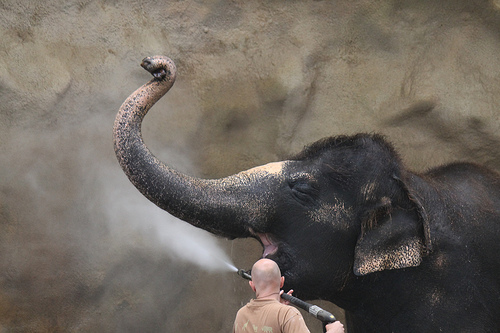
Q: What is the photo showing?
A: It is showing a zoo.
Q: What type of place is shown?
A: It is a zoo.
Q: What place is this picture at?
A: It is at the zoo.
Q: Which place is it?
A: It is a zoo.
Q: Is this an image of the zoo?
A: Yes, it is showing the zoo.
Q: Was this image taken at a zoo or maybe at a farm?
A: It was taken at a zoo.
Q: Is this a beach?
A: No, it is a zoo.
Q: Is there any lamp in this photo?
A: No, there are no lamps.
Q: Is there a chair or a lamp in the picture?
A: No, there are no lamps or chairs.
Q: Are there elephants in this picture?
A: Yes, there is an elephant.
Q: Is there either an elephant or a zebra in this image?
A: Yes, there is an elephant.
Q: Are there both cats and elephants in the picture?
A: No, there is an elephant but no cats.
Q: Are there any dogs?
A: No, there are no dogs.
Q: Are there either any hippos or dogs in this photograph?
A: No, there are no dogs or hippos.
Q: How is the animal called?
A: The animal is an elephant.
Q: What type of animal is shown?
A: The animal is an elephant.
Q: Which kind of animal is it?
A: The animal is an elephant.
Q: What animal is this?
A: That is an elephant.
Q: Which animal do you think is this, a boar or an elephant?
A: That is an elephant.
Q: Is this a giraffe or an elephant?
A: This is an elephant.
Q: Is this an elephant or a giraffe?
A: This is an elephant.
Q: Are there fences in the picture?
A: No, there are no fences.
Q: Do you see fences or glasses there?
A: No, there are no fences or glasses.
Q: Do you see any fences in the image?
A: No, there are no fences.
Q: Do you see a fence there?
A: No, there are no fences.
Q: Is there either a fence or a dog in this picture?
A: No, there are no fences or dogs.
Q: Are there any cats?
A: No, there are no cats.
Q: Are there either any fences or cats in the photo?
A: No, there are no cats or fences.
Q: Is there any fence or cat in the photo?
A: No, there are no cats or fences.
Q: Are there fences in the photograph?
A: No, there are no fences.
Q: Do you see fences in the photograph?
A: No, there are no fences.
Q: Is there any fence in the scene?
A: No, there are no fences.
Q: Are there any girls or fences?
A: No, there are no fences or girls.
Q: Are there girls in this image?
A: No, there are no girls.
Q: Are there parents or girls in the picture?
A: No, there are no girls or parents.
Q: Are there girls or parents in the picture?
A: No, there are no girls or parents.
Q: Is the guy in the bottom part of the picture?
A: Yes, the guy is in the bottom of the image.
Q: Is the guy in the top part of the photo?
A: No, the guy is in the bottom of the image.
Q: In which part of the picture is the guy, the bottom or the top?
A: The guy is in the bottom of the image.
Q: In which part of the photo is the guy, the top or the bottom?
A: The guy is in the bottom of the image.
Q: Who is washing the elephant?
A: The guy is washing the elephant.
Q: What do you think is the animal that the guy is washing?
A: The animal is an elephant.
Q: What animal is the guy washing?
A: The guy is washing the elephant.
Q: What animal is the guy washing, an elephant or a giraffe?
A: The guy is washing an elephant.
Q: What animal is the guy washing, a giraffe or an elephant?
A: The guy is washing an elephant.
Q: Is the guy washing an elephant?
A: Yes, the guy is washing an elephant.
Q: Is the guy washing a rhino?
A: No, the guy is washing an elephant.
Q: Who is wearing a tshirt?
A: The guy is wearing a tshirt.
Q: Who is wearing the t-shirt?
A: The guy is wearing a tshirt.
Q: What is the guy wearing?
A: The guy is wearing a tshirt.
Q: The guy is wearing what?
A: The guy is wearing a tshirt.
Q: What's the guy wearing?
A: The guy is wearing a tshirt.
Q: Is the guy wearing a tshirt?
A: Yes, the guy is wearing a tshirt.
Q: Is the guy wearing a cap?
A: No, the guy is wearing a tshirt.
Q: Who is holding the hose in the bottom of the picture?
A: The guy is holding the water hose.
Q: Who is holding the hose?
A: The guy is holding the water hose.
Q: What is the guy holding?
A: The guy is holding the hose.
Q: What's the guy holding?
A: The guy is holding the hose.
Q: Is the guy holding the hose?
A: Yes, the guy is holding the hose.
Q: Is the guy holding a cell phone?
A: No, the guy is holding the hose.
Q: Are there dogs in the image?
A: No, there are no dogs.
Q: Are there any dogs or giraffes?
A: No, there are no dogs or giraffes.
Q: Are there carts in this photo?
A: No, there are no carts.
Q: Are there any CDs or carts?
A: No, there are no carts or cds.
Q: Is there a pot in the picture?
A: No, there are no pots.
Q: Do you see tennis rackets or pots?
A: No, there are no pots or tennis rackets.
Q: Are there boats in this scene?
A: No, there are no boats.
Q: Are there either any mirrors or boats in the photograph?
A: No, there are no boats or mirrors.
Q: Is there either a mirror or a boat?
A: No, there are no boats or mirrors.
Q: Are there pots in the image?
A: No, there are no pots.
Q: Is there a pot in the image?
A: No, there are no pots.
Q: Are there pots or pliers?
A: No, there are no pots or pliers.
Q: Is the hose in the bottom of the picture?
A: Yes, the hose is in the bottom of the image.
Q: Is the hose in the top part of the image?
A: No, the hose is in the bottom of the image.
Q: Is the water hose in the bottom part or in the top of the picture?
A: The water hose is in the bottom of the image.